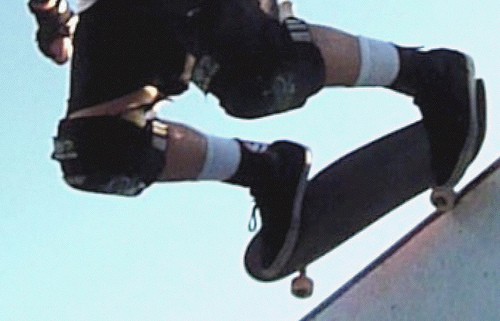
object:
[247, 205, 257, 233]
shoelace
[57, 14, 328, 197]
knee pads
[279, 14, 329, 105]
velcro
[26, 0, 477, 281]
skater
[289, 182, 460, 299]
wheels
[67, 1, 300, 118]
shorts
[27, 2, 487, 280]
skate boarder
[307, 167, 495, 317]
half pipe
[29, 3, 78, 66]
glove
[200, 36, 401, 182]
socks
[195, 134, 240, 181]
sock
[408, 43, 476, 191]
shoe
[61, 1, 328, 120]
black shorts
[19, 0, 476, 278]
man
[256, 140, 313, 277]
foot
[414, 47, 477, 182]
foot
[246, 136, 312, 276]
shoe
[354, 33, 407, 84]
sock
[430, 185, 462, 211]
wheel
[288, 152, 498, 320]
ramp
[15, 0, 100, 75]
wrist band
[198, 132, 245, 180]
cotton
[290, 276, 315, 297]
wheel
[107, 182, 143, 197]
brand name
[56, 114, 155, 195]
knee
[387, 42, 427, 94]
ankle band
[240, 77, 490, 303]
skateboard